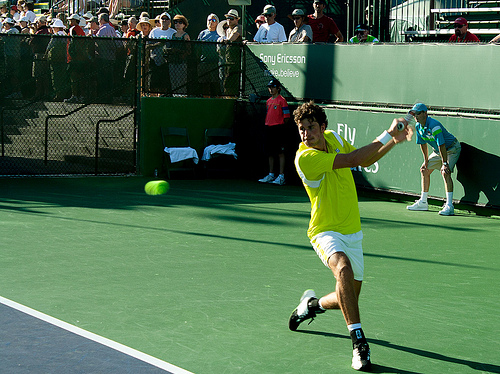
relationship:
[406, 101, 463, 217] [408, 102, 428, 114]
ball boy wearing blue hat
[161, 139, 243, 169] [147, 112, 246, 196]
towels on chairs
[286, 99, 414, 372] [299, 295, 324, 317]
man wearing socks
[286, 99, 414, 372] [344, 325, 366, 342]
man wearing socks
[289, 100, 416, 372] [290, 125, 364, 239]
man wearing man's shirt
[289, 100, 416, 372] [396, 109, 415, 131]
man holding racket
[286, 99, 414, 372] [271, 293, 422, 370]
man wearing shoes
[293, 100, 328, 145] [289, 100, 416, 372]
head of man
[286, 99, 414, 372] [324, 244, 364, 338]
man has leg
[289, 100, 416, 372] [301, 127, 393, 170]
man has arm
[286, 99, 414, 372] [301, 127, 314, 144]
man has nose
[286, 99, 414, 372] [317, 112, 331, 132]
man has ear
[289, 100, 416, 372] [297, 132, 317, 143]
man has mouth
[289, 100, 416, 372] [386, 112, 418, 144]
man has hand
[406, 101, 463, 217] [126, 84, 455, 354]
ball boy plays tennis match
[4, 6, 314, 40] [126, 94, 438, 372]
crowd at tennis match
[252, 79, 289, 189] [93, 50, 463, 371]
ball boy at tennis match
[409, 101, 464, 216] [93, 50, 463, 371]
ball boy at tennis match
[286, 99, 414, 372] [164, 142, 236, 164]
man has towels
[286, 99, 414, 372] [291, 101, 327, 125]
man has hair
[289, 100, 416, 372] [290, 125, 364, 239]
man wears man's shirt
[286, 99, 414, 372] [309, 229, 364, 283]
man wears man's shorts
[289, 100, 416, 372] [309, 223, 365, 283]
man has man's shorts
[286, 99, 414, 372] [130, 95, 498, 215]
man standing against wall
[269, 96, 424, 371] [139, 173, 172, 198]
athlete preparing to hit ball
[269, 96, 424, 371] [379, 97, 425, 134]
athlete with racket